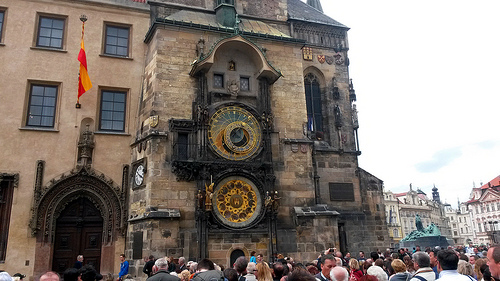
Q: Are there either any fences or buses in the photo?
A: No, there are no fences or buses.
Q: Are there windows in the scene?
A: Yes, there is a window.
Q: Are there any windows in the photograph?
A: Yes, there is a window.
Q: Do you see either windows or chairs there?
A: Yes, there is a window.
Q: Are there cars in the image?
A: No, there are no cars.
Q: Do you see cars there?
A: No, there are no cars.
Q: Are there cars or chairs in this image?
A: No, there are no cars or chairs.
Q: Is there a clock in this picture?
A: Yes, there is a clock.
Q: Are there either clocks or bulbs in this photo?
A: Yes, there is a clock.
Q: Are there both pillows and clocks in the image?
A: No, there is a clock but no pillows.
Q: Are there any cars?
A: No, there are no cars.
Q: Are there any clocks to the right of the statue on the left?
A: Yes, there is a clock to the right of the statue.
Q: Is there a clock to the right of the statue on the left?
A: Yes, there is a clock to the right of the statue.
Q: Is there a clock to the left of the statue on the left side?
A: No, the clock is to the right of the statue.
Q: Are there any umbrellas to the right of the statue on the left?
A: No, there is a clock to the right of the statue.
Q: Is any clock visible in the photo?
A: Yes, there is a clock.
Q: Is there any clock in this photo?
A: Yes, there is a clock.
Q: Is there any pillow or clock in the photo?
A: Yes, there is a clock.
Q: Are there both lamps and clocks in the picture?
A: No, there is a clock but no lamps.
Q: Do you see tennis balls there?
A: No, there are no tennis balls.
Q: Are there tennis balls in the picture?
A: No, there are no tennis balls.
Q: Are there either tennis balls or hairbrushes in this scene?
A: No, there are no tennis balls or hairbrushes.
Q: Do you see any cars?
A: No, there are no cars.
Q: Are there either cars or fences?
A: No, there are no cars or fences.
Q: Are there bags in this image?
A: No, there are no bags.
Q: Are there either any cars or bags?
A: No, there are no bags or cars.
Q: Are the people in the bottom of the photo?
A: Yes, the people are in the bottom of the image.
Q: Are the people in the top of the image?
A: No, the people are in the bottom of the image.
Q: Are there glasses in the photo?
A: No, there are no glasses.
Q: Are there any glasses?
A: No, there are no glasses.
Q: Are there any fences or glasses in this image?
A: No, there are no glasses or fences.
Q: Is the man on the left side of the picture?
A: Yes, the man is on the left of the image.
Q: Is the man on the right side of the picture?
A: No, the man is on the left of the image.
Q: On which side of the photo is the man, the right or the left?
A: The man is on the left of the image.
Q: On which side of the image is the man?
A: The man is on the left of the image.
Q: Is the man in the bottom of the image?
A: Yes, the man is in the bottom of the image.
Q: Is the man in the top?
A: No, the man is in the bottom of the image.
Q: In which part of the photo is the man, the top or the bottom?
A: The man is in the bottom of the image.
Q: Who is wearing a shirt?
A: The man is wearing a shirt.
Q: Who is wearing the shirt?
A: The man is wearing a shirt.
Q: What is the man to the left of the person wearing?
A: The man is wearing a shirt.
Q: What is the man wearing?
A: The man is wearing a shirt.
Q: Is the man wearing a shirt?
A: Yes, the man is wearing a shirt.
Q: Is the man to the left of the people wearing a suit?
A: No, the man is wearing a shirt.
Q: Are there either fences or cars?
A: No, there are no cars or fences.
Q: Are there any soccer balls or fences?
A: No, there are no fences or soccer balls.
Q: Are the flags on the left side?
A: Yes, the flags are on the left of the image.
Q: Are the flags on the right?
A: No, the flags are on the left of the image.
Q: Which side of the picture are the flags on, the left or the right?
A: The flags are on the left of the image.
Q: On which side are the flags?
A: The flags are on the left of the image.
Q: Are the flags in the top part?
A: Yes, the flags are in the top of the image.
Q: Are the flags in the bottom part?
A: No, the flags are in the top of the image.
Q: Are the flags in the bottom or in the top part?
A: The flags are in the top of the image.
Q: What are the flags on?
A: The flags are on the building.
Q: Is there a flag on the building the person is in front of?
A: Yes, there are flags on the building.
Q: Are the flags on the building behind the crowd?
A: Yes, the flags are on the building.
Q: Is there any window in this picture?
A: Yes, there is a window.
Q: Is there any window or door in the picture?
A: Yes, there is a window.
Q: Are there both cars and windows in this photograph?
A: No, there is a window but no cars.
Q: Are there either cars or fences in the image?
A: No, there are no cars or fences.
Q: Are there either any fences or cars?
A: No, there are no cars or fences.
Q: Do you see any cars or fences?
A: No, there are no cars or fences.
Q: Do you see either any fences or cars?
A: No, there are no cars or fences.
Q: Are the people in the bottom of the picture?
A: Yes, the people are in the bottom of the image.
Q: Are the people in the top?
A: No, the people are in the bottom of the image.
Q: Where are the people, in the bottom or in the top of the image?
A: The people are in the bottom of the image.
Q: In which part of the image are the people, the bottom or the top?
A: The people are in the bottom of the image.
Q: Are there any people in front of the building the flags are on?
A: Yes, there are people in front of the building.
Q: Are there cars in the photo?
A: No, there are no cars.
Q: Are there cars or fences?
A: No, there are no cars or fences.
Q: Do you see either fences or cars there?
A: No, there are no cars or fences.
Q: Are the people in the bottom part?
A: Yes, the people are in the bottom of the image.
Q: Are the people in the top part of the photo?
A: No, the people are in the bottom of the image.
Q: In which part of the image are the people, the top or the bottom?
A: The people are in the bottom of the image.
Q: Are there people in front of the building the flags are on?
A: Yes, there are people in front of the building.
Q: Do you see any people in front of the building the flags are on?
A: Yes, there are people in front of the building.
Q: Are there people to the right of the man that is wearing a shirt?
A: Yes, there are people to the right of the man.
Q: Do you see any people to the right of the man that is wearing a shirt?
A: Yes, there are people to the right of the man.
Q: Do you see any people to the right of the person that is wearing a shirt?
A: Yes, there are people to the right of the man.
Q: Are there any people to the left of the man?
A: No, the people are to the right of the man.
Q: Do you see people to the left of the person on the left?
A: No, the people are to the right of the man.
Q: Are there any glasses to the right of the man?
A: No, there are people to the right of the man.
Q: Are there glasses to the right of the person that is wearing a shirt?
A: No, there are people to the right of the man.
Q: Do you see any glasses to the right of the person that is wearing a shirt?
A: No, there are people to the right of the man.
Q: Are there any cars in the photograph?
A: No, there are no cars.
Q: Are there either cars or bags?
A: No, there are no cars or bags.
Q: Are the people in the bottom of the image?
A: Yes, the people are in the bottom of the image.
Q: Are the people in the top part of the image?
A: No, the people are in the bottom of the image.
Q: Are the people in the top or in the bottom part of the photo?
A: The people are in the bottom of the image.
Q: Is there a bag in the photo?
A: No, there are no bags.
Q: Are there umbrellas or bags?
A: No, there are no bags or umbrellas.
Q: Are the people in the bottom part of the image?
A: Yes, the people are in the bottom of the image.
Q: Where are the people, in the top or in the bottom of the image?
A: The people are in the bottom of the image.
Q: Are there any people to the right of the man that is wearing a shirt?
A: Yes, there are people to the right of the man.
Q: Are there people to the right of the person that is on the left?
A: Yes, there are people to the right of the man.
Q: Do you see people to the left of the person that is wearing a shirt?
A: No, the people are to the right of the man.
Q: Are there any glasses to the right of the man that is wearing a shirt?
A: No, there are people to the right of the man.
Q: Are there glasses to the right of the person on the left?
A: No, there are people to the right of the man.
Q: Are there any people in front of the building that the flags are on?
A: Yes, there are people in front of the building.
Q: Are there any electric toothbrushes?
A: No, there are no electric toothbrushes.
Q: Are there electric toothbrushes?
A: No, there are no electric toothbrushes.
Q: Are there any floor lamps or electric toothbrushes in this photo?
A: No, there are no electric toothbrushes or floor lamps.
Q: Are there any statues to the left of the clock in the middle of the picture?
A: Yes, there is a statue to the left of the clock.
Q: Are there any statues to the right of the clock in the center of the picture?
A: No, the statue is to the left of the clock.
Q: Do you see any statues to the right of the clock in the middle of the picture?
A: No, the statue is to the left of the clock.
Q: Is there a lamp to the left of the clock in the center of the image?
A: No, there is a statue to the left of the clock.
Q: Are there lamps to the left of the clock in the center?
A: No, there is a statue to the left of the clock.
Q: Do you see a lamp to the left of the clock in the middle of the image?
A: No, there is a statue to the left of the clock.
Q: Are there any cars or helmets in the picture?
A: No, there are no cars or helmets.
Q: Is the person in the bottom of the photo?
A: Yes, the person is in the bottom of the image.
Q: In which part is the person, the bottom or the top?
A: The person is in the bottom of the image.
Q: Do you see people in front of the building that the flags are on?
A: Yes, there is a person in front of the building.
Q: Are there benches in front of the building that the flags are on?
A: No, there is a person in front of the building.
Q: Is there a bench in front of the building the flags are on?
A: No, there is a person in front of the building.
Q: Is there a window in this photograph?
A: Yes, there is a window.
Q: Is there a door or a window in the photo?
A: Yes, there is a window.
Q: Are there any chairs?
A: No, there are no chairs.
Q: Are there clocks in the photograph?
A: Yes, there is a clock.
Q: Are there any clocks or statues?
A: Yes, there is a clock.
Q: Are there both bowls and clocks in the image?
A: No, there is a clock but no bowls.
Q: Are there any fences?
A: No, there are no fences.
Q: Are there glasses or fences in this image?
A: No, there are no fences or glasses.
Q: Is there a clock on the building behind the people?
A: Yes, there is a clock on the building.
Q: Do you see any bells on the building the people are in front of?
A: No, there is a clock on the building.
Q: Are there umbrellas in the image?
A: No, there are no umbrellas.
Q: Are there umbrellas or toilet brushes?
A: No, there are no umbrellas or toilet brushes.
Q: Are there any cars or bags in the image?
A: No, there are no cars or bags.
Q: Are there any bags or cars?
A: No, there are no cars or bags.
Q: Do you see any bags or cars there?
A: No, there are no cars or bags.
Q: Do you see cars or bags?
A: No, there are no cars or bags.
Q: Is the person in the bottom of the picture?
A: Yes, the person is in the bottom of the image.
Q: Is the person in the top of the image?
A: No, the person is in the bottom of the image.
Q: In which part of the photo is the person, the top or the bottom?
A: The person is in the bottom of the image.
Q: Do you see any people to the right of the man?
A: Yes, there is a person to the right of the man.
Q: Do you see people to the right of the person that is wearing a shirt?
A: Yes, there is a person to the right of the man.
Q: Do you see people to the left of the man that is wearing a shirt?
A: No, the person is to the right of the man.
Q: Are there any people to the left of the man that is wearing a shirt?
A: No, the person is to the right of the man.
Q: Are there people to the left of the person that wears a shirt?
A: No, the person is to the right of the man.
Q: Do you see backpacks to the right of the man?
A: No, there is a person to the right of the man.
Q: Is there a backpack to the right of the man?
A: No, there is a person to the right of the man.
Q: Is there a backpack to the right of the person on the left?
A: No, there is a person to the right of the man.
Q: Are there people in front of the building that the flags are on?
A: Yes, there is a person in front of the building.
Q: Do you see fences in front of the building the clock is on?
A: No, there is a person in front of the building.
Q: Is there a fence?
A: No, there are no fences.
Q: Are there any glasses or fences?
A: No, there are no fences or glasses.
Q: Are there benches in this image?
A: No, there are no benches.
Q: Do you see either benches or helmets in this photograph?
A: No, there are no benches or helmets.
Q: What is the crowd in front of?
A: The crowd is in front of the building.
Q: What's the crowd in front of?
A: The crowd is in front of the building.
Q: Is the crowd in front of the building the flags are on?
A: Yes, the crowd is in front of the building.